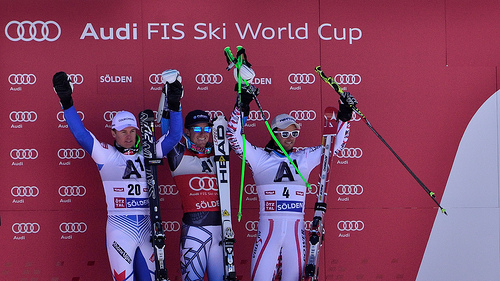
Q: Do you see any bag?
A: No, there are no bags.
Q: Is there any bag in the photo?
A: No, there are no bags.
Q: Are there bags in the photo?
A: No, there are no bags.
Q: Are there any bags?
A: No, there are no bags.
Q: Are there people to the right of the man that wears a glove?
A: Yes, there is a person to the right of the man.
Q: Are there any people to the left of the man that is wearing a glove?
A: No, the person is to the right of the man.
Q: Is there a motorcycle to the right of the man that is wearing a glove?
A: No, there is a person to the right of the man.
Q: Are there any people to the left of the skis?
A: No, the person is to the right of the skis.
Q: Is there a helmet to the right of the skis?
A: No, there is a person to the right of the skis.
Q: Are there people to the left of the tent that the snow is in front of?
A: Yes, there is a person to the left of the tent.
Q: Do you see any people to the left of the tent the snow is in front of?
A: Yes, there is a person to the left of the tent.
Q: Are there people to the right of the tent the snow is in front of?
A: No, the person is to the left of the tent.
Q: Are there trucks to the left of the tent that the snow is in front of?
A: No, there is a person to the left of the tent.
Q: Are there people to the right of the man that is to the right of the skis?
A: Yes, there is a person to the right of the man.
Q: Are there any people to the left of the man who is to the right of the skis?
A: No, the person is to the right of the man.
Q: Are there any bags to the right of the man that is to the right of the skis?
A: No, there is a person to the right of the man.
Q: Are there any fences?
A: No, there are no fences.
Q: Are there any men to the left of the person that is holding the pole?
A: Yes, there is a man to the left of the person.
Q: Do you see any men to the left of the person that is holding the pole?
A: Yes, there is a man to the left of the person.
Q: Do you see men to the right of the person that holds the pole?
A: No, the man is to the left of the person.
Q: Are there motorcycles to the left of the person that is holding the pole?
A: No, there is a man to the left of the person.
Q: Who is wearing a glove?
A: The man is wearing a glove.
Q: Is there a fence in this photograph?
A: No, there are no fences.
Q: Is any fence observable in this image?
A: No, there are no fences.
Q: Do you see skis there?
A: Yes, there are skis.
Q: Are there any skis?
A: Yes, there are skis.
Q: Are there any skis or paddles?
A: Yes, there are skis.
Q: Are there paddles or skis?
A: Yes, there are skis.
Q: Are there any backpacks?
A: No, there are no backpacks.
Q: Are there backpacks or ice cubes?
A: No, there are no backpacks or ice cubes.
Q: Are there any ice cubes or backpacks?
A: No, there are no backpacks or ice cubes.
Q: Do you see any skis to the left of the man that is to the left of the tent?
A: Yes, there are skis to the left of the man.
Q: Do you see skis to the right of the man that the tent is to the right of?
A: No, the skis are to the left of the man.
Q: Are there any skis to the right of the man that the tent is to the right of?
A: No, the skis are to the left of the man.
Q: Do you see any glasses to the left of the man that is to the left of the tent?
A: No, there are skis to the left of the man.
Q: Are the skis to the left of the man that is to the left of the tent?
A: Yes, the skis are to the left of the man.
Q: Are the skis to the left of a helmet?
A: No, the skis are to the left of the man.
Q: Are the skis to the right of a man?
A: No, the skis are to the left of a man.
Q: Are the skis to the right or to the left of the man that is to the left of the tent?
A: The skis are to the left of the man.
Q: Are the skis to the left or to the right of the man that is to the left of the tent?
A: The skis are to the left of the man.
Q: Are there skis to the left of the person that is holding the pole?
A: Yes, there are skis to the left of the person.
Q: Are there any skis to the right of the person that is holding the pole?
A: No, the skis are to the left of the person.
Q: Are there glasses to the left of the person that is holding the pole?
A: No, there are skis to the left of the person.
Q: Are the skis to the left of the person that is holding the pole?
A: Yes, the skis are to the left of the person.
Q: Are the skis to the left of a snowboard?
A: No, the skis are to the left of the person.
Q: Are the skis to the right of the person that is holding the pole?
A: No, the skis are to the left of the person.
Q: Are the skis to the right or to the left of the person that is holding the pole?
A: The skis are to the left of the person.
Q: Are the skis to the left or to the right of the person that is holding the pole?
A: The skis are to the left of the person.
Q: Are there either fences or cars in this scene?
A: No, there are no fences or cars.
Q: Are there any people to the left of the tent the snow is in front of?
A: Yes, there are people to the left of the tent.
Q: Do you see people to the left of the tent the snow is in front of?
A: Yes, there are people to the left of the tent.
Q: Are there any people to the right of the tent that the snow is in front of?
A: No, the people are to the left of the tent.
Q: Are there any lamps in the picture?
A: No, there are no lamps.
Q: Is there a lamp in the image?
A: No, there are no lamps.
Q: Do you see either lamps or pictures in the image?
A: No, there are no lamps or pictures.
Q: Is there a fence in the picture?
A: No, there are no fences.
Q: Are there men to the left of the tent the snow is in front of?
A: Yes, there is a man to the left of the tent.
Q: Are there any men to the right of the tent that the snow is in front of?
A: No, the man is to the left of the tent.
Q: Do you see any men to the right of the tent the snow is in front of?
A: No, the man is to the left of the tent.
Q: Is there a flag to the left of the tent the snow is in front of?
A: No, there is a man to the left of the tent.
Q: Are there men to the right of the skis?
A: Yes, there is a man to the right of the skis.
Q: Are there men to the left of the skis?
A: No, the man is to the right of the skis.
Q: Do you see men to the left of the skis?
A: No, the man is to the right of the skis.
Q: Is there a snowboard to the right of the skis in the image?
A: No, there is a man to the right of the skis.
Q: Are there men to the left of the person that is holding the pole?
A: Yes, there is a man to the left of the person.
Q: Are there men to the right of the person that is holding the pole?
A: No, the man is to the left of the person.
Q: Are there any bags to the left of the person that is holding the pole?
A: No, there is a man to the left of the person.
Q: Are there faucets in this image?
A: No, there are no faucets.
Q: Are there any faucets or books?
A: No, there are no faucets or books.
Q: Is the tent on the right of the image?
A: Yes, the tent is on the right of the image.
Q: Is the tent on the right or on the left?
A: The tent is on the right of the image.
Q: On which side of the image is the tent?
A: The tent is on the right of the image.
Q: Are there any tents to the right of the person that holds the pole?
A: Yes, there is a tent to the right of the person.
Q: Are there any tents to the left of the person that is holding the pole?
A: No, the tent is to the right of the person.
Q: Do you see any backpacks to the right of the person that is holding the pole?
A: No, there is a tent to the right of the person.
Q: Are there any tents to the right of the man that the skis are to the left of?
A: Yes, there is a tent to the right of the man.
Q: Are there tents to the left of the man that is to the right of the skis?
A: No, the tent is to the right of the man.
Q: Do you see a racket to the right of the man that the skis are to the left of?
A: No, there is a tent to the right of the man.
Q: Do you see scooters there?
A: No, there are no scooters.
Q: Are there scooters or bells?
A: No, there are no scooters or bells.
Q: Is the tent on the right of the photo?
A: Yes, the tent is on the right of the image.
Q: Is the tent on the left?
A: No, the tent is on the right of the image.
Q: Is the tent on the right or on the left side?
A: The tent is on the right of the image.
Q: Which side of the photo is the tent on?
A: The tent is on the right of the image.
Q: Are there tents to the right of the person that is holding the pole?
A: Yes, there is a tent to the right of the person.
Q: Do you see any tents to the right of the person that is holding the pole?
A: Yes, there is a tent to the right of the person.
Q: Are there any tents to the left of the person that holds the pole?
A: No, the tent is to the right of the person.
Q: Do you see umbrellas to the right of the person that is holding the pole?
A: No, there is a tent to the right of the person.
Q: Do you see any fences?
A: No, there are no fences.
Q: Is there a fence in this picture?
A: No, there are no fences.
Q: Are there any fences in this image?
A: No, there are no fences.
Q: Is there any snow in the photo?
A: Yes, there is snow.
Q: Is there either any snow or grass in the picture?
A: Yes, there is snow.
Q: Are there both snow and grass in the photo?
A: No, there is snow but no grass.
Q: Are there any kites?
A: No, there are no kites.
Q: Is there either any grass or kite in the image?
A: No, there are no kites or grass.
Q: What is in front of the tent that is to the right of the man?
A: The snow is in front of the tent.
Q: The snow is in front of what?
A: The snow is in front of the tent.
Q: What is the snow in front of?
A: The snow is in front of the tent.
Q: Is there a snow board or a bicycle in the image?
A: No, there are no snowboards or bicycles.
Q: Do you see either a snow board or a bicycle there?
A: No, there are no snowboards or bicycles.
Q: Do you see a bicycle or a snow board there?
A: No, there are no snowboards or bicycles.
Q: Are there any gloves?
A: Yes, there are gloves.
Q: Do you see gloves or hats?
A: Yes, there are gloves.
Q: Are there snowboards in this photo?
A: No, there are no snowboards.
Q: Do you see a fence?
A: No, there are no fences.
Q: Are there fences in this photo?
A: No, there are no fences.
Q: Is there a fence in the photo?
A: No, there are no fences.